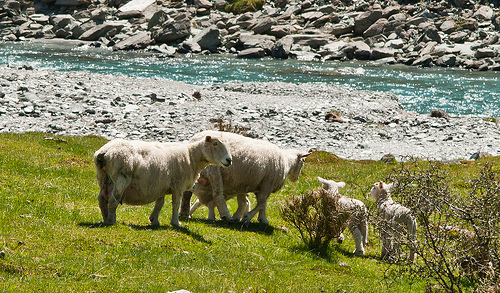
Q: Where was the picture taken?
A: It was taken at the river.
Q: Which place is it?
A: It is a river.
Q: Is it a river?
A: Yes, it is a river.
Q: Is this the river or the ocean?
A: It is the river.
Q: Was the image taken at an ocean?
A: No, the picture was taken in a river.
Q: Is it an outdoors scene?
A: Yes, it is outdoors.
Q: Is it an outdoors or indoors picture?
A: It is outdoors.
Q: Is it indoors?
A: No, it is outdoors.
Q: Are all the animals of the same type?
A: No, there are both sheep and cows.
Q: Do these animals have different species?
A: Yes, they are sheep and cows.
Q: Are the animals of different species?
A: Yes, they are sheep and cows.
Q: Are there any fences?
A: No, there are no fences.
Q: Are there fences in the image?
A: No, there are no fences.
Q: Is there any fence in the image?
A: No, there are no fences.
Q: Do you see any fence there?
A: No, there are no fences.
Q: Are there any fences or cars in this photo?
A: No, there are no fences or cars.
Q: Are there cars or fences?
A: No, there are no fences or cars.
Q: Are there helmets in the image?
A: No, there are no helmets.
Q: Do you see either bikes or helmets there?
A: No, there are no helmets or bikes.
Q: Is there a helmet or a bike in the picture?
A: No, there are no helmets or bikes.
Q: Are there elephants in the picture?
A: No, there are no elephants.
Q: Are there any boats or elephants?
A: No, there are no elephants or boats.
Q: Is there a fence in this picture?
A: No, there are no fences.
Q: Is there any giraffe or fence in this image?
A: No, there are no fences or giraffes.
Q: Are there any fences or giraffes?
A: No, there are no fences or giraffes.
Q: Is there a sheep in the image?
A: Yes, there is a sheep.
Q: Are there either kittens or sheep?
A: Yes, there is a sheep.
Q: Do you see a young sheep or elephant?
A: Yes, there is a young sheep.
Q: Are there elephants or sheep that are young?
A: Yes, the sheep is young.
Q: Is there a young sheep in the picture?
A: Yes, there is a young sheep.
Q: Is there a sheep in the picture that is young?
A: Yes, there is a sheep that is young.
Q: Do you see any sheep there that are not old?
A: Yes, there is an young sheep.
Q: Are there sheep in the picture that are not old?
A: Yes, there is an young sheep.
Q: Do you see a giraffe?
A: No, there are no giraffes.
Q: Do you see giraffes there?
A: No, there are no giraffes.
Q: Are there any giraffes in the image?
A: No, there are no giraffes.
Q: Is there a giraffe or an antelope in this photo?
A: No, there are no giraffes or antelopes.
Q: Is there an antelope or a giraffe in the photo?
A: No, there are no giraffes or antelopes.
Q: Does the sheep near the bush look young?
A: Yes, the sheep is young.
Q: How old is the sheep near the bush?
A: The sheep is young.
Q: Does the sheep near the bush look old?
A: No, the sheep is young.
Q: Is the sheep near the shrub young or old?
A: The sheep is young.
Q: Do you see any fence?
A: No, there are no fences.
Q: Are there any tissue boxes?
A: No, there are no tissue boxes.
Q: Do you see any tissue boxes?
A: No, there are no tissue boxes.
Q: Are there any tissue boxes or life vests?
A: No, there are no tissue boxes or life vests.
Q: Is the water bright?
A: Yes, the water is bright.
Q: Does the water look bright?
A: Yes, the water is bright.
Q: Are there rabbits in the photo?
A: No, there are no rabbits.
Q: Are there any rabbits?
A: No, there are no rabbits.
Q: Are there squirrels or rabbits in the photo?
A: No, there are no rabbits or squirrels.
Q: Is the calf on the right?
A: Yes, the calf is on the right of the image.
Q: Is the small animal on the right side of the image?
A: Yes, the calf is on the right of the image.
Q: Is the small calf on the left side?
A: No, the calf is on the right of the image.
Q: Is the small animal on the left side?
A: No, the calf is on the right of the image.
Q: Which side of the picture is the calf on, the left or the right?
A: The calf is on the right of the image.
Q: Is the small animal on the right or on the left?
A: The calf is on the right of the image.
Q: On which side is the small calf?
A: The calf is on the right of the image.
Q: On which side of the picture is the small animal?
A: The calf is on the right of the image.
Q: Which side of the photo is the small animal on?
A: The calf is on the right of the image.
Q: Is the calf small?
A: Yes, the calf is small.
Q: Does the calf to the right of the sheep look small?
A: Yes, the calf is small.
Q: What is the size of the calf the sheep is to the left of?
A: The calf is small.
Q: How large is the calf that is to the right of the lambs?
A: The calf is small.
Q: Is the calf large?
A: No, the calf is small.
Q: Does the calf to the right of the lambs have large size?
A: No, the calf is small.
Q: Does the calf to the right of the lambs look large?
A: No, the calf is small.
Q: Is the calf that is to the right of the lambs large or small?
A: The calf is small.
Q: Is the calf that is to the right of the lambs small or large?
A: The calf is small.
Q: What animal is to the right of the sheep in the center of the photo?
A: The animal is a calf.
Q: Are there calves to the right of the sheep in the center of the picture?
A: Yes, there is a calf to the right of the sheep.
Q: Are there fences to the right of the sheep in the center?
A: No, there is a calf to the right of the sheep.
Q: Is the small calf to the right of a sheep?
A: Yes, the calf is to the right of a sheep.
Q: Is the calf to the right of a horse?
A: No, the calf is to the right of a sheep.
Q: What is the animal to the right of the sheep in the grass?
A: The animal is a calf.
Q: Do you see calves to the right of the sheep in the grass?
A: Yes, there is a calf to the right of the sheep.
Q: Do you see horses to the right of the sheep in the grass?
A: No, there is a calf to the right of the sheep.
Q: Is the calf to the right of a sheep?
A: Yes, the calf is to the right of a sheep.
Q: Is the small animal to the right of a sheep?
A: Yes, the calf is to the right of a sheep.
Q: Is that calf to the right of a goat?
A: No, the calf is to the right of a sheep.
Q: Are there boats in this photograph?
A: No, there are no boats.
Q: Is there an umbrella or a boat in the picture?
A: No, there are no boats or umbrellas.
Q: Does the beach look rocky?
A: Yes, the beach is rocky.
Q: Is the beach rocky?
A: Yes, the beach is rocky.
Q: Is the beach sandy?
A: No, the beach is rocky.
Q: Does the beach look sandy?
A: No, the beach is rocky.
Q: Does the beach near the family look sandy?
A: No, the beach is rocky.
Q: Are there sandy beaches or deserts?
A: No, there is a beach but it is rocky.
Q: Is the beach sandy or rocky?
A: The beach is rocky.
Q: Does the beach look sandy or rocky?
A: The beach is rocky.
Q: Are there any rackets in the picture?
A: No, there are no rackets.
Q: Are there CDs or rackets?
A: No, there are no rackets or cds.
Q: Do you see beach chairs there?
A: No, there are no beach chairs.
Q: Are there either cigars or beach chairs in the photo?
A: No, there are no beach chairs or cigars.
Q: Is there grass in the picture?
A: Yes, there is grass.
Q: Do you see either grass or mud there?
A: Yes, there is grass.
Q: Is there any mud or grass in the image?
A: Yes, there is grass.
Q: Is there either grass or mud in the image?
A: Yes, there is grass.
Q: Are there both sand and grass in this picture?
A: No, there is grass but no sand.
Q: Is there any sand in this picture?
A: No, there is no sand.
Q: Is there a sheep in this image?
A: Yes, there is a sheep.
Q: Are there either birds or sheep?
A: Yes, there is a sheep.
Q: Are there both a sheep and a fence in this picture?
A: No, there is a sheep but no fences.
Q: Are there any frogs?
A: No, there are no frogs.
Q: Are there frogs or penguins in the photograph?
A: No, there are no frogs or penguins.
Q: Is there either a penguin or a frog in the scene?
A: No, there are no frogs or penguins.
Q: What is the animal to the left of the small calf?
A: The animal is a sheep.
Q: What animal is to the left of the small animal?
A: The animal is a sheep.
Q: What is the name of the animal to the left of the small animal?
A: The animal is a sheep.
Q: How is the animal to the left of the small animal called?
A: The animal is a sheep.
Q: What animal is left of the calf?
A: The animal is a sheep.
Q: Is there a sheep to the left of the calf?
A: Yes, there is a sheep to the left of the calf.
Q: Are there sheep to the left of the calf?
A: Yes, there is a sheep to the left of the calf.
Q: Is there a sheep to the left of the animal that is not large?
A: Yes, there is a sheep to the left of the calf.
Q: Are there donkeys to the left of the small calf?
A: No, there is a sheep to the left of the calf.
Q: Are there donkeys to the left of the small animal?
A: No, there is a sheep to the left of the calf.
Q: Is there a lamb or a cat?
A: Yes, there is a lamb.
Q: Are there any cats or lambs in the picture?
A: Yes, there is a lamb.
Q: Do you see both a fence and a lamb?
A: No, there is a lamb but no fences.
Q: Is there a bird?
A: No, there are no birds.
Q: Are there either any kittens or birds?
A: No, there are no birds or kittens.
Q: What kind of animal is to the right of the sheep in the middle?
A: The animal is a lamb.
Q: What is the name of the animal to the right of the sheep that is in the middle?
A: The animal is a lamb.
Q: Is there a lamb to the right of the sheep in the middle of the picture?
A: Yes, there is a lamb to the right of the sheep.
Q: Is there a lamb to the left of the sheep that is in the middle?
A: No, the lamb is to the right of the sheep.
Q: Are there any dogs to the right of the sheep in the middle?
A: No, there is a lamb to the right of the sheep.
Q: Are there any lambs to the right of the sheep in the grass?
A: Yes, there is a lamb to the right of the sheep.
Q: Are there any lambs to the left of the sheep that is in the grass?
A: No, the lamb is to the right of the sheep.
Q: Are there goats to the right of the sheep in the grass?
A: No, there is a lamb to the right of the sheep.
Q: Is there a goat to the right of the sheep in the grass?
A: No, there is a lamb to the right of the sheep.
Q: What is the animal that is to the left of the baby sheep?
A: The animal is a lamb.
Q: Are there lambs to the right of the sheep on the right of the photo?
A: No, the lamb is to the left of the sheep.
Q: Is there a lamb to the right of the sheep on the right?
A: No, the lamb is to the left of the sheep.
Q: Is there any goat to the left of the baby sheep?
A: No, there is a lamb to the left of the sheep.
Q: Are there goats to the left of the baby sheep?
A: No, there is a lamb to the left of the sheep.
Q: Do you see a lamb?
A: Yes, there are lambs.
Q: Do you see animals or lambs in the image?
A: Yes, there are lambs.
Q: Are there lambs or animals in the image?
A: Yes, there are lambs.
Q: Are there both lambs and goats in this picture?
A: No, there are lambs but no goats.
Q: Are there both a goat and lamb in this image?
A: No, there are lambs but no goats.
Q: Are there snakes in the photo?
A: No, there are no snakes.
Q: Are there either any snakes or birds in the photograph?
A: No, there are no snakes or birds.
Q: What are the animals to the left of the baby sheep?
A: The animals are lambs.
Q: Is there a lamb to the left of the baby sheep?
A: Yes, there are lambs to the left of the sheep.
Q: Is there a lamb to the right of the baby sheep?
A: No, the lambs are to the left of the sheep.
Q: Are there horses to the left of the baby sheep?
A: No, there are lambs to the left of the sheep.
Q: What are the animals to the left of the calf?
A: The animals are lambs.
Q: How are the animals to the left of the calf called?
A: The animals are lambs.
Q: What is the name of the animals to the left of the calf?
A: The animals are lambs.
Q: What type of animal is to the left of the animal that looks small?
A: The animals are lambs.